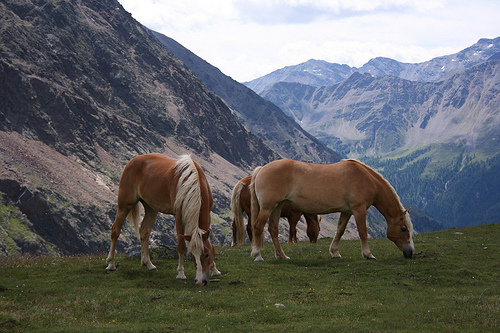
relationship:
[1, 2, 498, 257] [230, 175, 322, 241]
mountain range behind horse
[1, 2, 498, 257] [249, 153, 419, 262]
mountain range behind horse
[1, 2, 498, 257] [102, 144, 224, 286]
mountain range behind horse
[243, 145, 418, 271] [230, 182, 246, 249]
horse has white tail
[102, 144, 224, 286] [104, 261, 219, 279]
horse has hooves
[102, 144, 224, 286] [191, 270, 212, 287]
horse has nose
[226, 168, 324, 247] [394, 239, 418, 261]
horse has nose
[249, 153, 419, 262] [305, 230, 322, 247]
horse has nose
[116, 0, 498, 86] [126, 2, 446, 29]
sky has clouds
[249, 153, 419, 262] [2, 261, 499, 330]
horse grazing on grass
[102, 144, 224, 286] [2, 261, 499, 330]
horse grazing on grass